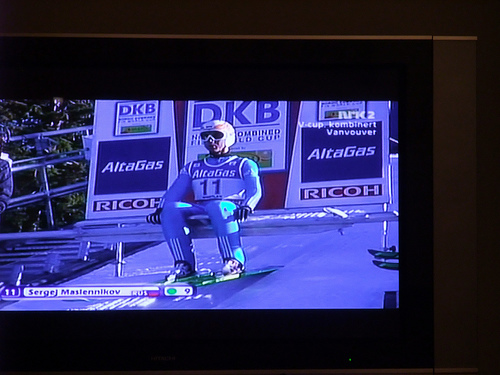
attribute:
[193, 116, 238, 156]
helmet — white, ski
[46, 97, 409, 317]
screen — part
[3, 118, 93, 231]
rail — silver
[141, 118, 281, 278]
skier — green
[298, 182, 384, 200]
sign — red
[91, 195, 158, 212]
sign — red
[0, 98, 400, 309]
screen — part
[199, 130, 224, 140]
goggles — black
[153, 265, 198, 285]
ski — green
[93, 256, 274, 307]
green skis — green 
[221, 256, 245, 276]
ski boot — white, blue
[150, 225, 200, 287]
boot — blue, white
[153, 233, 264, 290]
shoes — black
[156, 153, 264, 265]
outfit — blue , white 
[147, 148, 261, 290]
suit — blue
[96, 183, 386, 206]
letters — white 